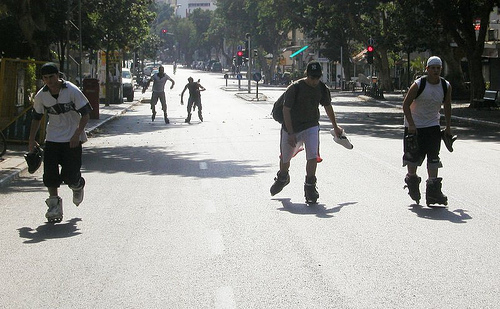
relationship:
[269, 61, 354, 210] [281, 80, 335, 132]
guy in shirt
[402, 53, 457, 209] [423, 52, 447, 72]
guy in hat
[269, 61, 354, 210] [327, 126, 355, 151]
guy holding shoes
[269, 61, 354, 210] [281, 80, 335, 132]
guy wearing shirt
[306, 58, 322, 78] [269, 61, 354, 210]
hat on guy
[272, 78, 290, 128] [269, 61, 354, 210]
backback on guy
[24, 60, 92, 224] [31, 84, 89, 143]
man wearing shirt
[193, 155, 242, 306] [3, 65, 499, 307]
line on street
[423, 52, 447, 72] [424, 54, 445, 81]
hat on head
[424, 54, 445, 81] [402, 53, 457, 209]
head on guy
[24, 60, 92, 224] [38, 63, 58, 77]
man in hat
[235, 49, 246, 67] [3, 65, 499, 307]
light in middle of road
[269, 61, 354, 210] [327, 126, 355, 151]
guy carrying shoes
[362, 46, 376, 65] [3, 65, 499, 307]
light on side of street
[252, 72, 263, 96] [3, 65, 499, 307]
sign in middle of street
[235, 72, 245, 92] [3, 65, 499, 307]
sign in middle of street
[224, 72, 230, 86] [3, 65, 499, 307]
sign in middle of street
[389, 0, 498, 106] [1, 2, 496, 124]
tree in background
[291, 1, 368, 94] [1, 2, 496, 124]
tree in background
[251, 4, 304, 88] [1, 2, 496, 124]
tree in background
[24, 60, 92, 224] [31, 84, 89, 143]
man in shirt